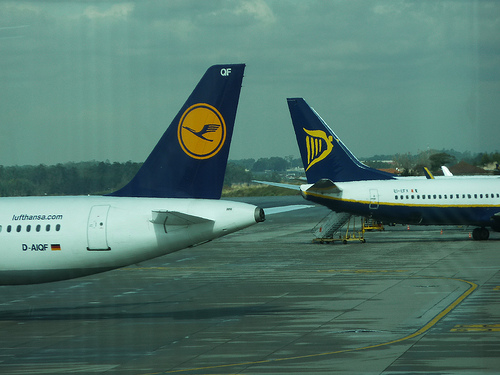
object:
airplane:
[0, 62, 267, 287]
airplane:
[285, 97, 499, 245]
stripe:
[303, 193, 499, 206]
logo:
[177, 103, 227, 161]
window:
[15, 222, 23, 234]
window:
[7, 224, 12, 232]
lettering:
[12, 213, 63, 221]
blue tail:
[104, 62, 246, 197]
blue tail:
[284, 97, 397, 181]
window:
[400, 195, 405, 200]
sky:
[0, 0, 499, 166]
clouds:
[1, 0, 498, 168]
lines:
[413, 312, 440, 340]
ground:
[163, 298, 223, 368]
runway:
[4, 197, 499, 368]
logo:
[303, 126, 334, 172]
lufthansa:
[11, 212, 63, 221]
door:
[369, 189, 380, 210]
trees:
[4, 152, 496, 194]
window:
[55, 224, 60, 232]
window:
[45, 224, 50, 232]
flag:
[50, 244, 61, 252]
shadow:
[3, 294, 312, 323]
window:
[26, 225, 31, 233]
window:
[394, 195, 398, 200]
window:
[422, 194, 426, 199]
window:
[432, 195, 437, 200]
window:
[35, 224, 41, 233]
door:
[85, 204, 111, 252]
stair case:
[310, 209, 368, 245]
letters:
[220, 68, 231, 77]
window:
[16, 225, 22, 233]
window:
[411, 194, 415, 200]